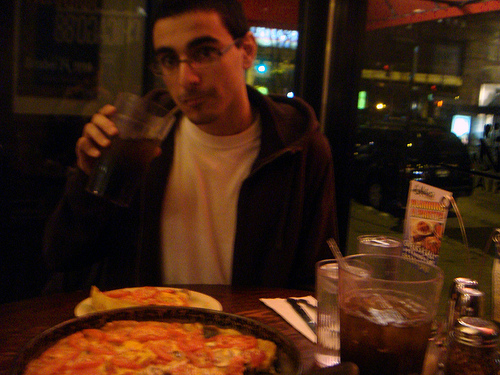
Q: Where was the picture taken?
A: It was taken at the restaurant.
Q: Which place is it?
A: It is a restaurant.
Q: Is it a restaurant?
A: Yes, it is a restaurant.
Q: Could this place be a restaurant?
A: Yes, it is a restaurant.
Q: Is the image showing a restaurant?
A: Yes, it is showing a restaurant.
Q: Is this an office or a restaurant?
A: It is a restaurant.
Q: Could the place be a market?
A: No, it is a restaurant.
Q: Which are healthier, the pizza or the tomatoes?
A: The tomatoes are healthier than the pizza.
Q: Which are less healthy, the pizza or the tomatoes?
A: The pizza are less healthy than the tomatoes.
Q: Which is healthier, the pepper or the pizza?
A: The pepper is healthier than the pizza.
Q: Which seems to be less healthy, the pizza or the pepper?
A: The pizza is less healthy than the pepper.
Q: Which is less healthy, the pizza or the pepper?
A: The pizza is less healthy than the pepper.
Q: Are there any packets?
A: No, there are no packets.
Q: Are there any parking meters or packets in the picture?
A: No, there are no packets or parking meters.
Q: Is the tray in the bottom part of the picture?
A: Yes, the tray is in the bottom of the image.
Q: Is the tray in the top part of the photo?
A: No, the tray is in the bottom of the image.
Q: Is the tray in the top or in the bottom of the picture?
A: The tray is in the bottom of the image.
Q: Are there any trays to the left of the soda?
A: Yes, there is a tray to the left of the soda.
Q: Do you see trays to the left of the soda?
A: Yes, there is a tray to the left of the soda.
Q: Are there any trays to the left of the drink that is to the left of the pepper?
A: Yes, there is a tray to the left of the soda.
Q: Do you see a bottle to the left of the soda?
A: No, there is a tray to the left of the soda.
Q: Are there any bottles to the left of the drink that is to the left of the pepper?
A: No, there is a tray to the left of the soda.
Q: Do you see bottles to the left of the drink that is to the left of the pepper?
A: No, there is a tray to the left of the soda.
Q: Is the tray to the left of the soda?
A: Yes, the tray is to the left of the soda.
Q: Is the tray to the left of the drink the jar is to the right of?
A: Yes, the tray is to the left of the soda.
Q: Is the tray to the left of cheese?
A: No, the tray is to the left of the soda.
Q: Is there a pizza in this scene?
A: Yes, there is a pizza.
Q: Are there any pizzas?
A: Yes, there is a pizza.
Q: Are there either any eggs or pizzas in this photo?
A: Yes, there is a pizza.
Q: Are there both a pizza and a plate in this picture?
A: Yes, there are both a pizza and a plate.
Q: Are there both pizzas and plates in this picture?
A: Yes, there are both a pizza and a plate.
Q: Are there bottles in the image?
A: No, there are no bottles.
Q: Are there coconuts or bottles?
A: No, there are no bottles or coconuts.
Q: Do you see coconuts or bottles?
A: No, there are no bottles or coconuts.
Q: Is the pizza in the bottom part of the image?
A: Yes, the pizza is in the bottom of the image.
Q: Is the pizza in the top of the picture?
A: No, the pizza is in the bottom of the image.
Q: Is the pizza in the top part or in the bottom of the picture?
A: The pizza is in the bottom of the image.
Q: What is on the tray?
A: The pizza is on the tray.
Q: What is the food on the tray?
A: The food is a pizza.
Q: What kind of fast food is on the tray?
A: The food is a pizza.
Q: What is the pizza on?
A: The pizza is on the tray.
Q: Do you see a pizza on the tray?
A: Yes, there is a pizza on the tray.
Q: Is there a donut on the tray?
A: No, there is a pizza on the tray.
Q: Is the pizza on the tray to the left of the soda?
A: Yes, the pizza is on the tray.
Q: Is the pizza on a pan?
A: No, the pizza is on the tray.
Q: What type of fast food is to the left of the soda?
A: The food is a pizza.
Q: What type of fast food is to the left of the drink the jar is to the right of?
A: The food is a pizza.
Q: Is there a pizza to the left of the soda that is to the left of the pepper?
A: Yes, there is a pizza to the left of the soda.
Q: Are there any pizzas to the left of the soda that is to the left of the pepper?
A: Yes, there is a pizza to the left of the soda.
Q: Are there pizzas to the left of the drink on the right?
A: Yes, there is a pizza to the left of the soda.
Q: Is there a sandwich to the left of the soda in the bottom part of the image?
A: No, there is a pizza to the left of the soda.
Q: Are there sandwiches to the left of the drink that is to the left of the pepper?
A: No, there is a pizza to the left of the soda.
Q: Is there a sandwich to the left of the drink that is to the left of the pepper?
A: No, there is a pizza to the left of the soda.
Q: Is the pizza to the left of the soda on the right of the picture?
A: Yes, the pizza is to the left of the soda.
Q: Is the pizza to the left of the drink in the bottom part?
A: Yes, the pizza is to the left of the soda.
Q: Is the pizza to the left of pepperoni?
A: No, the pizza is to the left of the soda.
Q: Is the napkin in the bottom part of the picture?
A: Yes, the napkin is in the bottom of the image.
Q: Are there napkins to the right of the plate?
A: Yes, there is a napkin to the right of the plate.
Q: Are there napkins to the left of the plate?
A: No, the napkin is to the right of the plate.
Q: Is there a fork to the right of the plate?
A: No, there is a napkin to the right of the plate.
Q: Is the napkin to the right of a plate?
A: Yes, the napkin is to the right of a plate.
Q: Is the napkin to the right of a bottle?
A: No, the napkin is to the right of a plate.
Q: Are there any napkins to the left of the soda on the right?
A: Yes, there is a napkin to the left of the soda.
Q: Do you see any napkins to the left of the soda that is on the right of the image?
A: Yes, there is a napkin to the left of the soda.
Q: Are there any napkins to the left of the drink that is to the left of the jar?
A: Yes, there is a napkin to the left of the soda.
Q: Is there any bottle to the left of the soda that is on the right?
A: No, there is a napkin to the left of the soda.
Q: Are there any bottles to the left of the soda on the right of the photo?
A: No, there is a napkin to the left of the soda.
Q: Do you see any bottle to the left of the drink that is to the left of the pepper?
A: No, there is a napkin to the left of the soda.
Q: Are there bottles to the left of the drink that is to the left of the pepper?
A: No, there is a napkin to the left of the soda.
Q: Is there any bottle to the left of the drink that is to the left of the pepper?
A: No, there is a napkin to the left of the soda.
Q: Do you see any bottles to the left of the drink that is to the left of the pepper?
A: No, there is a napkin to the left of the soda.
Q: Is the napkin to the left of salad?
A: No, the napkin is to the left of the soda.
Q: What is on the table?
A: The napkin is on the table.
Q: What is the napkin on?
A: The napkin is on the table.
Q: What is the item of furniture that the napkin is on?
A: The piece of furniture is a table.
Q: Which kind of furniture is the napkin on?
A: The napkin is on the table.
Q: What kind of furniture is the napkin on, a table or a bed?
A: The napkin is on a table.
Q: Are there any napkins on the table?
A: Yes, there is a napkin on the table.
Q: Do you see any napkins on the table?
A: Yes, there is a napkin on the table.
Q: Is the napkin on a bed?
A: No, the napkin is on the table.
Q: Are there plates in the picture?
A: Yes, there is a plate.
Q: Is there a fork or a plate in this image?
A: Yes, there is a plate.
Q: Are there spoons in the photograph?
A: No, there are no spoons.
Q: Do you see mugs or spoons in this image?
A: No, there are no spoons or mugs.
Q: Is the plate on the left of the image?
A: Yes, the plate is on the left of the image.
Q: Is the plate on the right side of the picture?
A: No, the plate is on the left of the image.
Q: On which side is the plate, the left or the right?
A: The plate is on the left of the image.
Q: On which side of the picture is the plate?
A: The plate is on the left of the image.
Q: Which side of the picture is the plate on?
A: The plate is on the left of the image.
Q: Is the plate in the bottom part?
A: Yes, the plate is in the bottom of the image.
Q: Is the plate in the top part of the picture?
A: No, the plate is in the bottom of the image.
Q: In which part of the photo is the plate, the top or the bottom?
A: The plate is in the bottom of the image.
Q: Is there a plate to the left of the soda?
A: Yes, there is a plate to the left of the soda.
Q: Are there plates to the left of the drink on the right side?
A: Yes, there is a plate to the left of the soda.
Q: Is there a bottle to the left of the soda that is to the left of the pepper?
A: No, there is a plate to the left of the soda.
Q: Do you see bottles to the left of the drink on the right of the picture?
A: No, there is a plate to the left of the soda.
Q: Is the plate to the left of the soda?
A: Yes, the plate is to the left of the soda.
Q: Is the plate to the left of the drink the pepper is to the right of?
A: Yes, the plate is to the left of the soda.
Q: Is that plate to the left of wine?
A: No, the plate is to the left of the soda.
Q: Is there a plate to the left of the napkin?
A: Yes, there is a plate to the left of the napkin.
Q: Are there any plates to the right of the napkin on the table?
A: No, the plate is to the left of the napkin.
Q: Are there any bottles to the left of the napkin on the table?
A: No, there is a plate to the left of the napkin.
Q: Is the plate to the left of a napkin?
A: Yes, the plate is to the left of a napkin.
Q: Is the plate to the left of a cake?
A: No, the plate is to the left of a napkin.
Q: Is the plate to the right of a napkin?
A: No, the plate is to the left of a napkin.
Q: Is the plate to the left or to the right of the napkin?
A: The plate is to the left of the napkin.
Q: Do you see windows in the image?
A: Yes, there is a window.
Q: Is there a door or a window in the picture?
A: Yes, there is a window.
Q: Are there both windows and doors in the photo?
A: No, there is a window but no doors.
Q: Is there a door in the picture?
A: No, there are no doors.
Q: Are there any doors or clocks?
A: No, there are no doors or clocks.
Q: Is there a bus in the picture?
A: No, there are no buses.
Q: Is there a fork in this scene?
A: No, there are no forks.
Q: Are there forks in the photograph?
A: No, there are no forks.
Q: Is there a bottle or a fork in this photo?
A: No, there are no forks or bottles.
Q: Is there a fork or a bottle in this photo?
A: No, there are no forks or bottles.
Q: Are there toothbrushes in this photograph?
A: No, there are no toothbrushes.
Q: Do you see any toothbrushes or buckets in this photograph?
A: No, there are no toothbrushes or buckets.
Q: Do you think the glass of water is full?
A: Yes, the glass is full.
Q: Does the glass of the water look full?
A: Yes, the glass is full.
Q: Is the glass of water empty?
A: No, the glass is full.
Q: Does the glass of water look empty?
A: No, the glass is full.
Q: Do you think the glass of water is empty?
A: No, the glass is full.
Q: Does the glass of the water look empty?
A: No, the glass is full.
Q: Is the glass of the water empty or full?
A: The glass is full.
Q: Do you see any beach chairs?
A: No, there are no beach chairs.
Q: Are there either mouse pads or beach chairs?
A: No, there are no beach chairs or mouse pads.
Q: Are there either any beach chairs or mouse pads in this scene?
A: No, there are no beach chairs or mouse pads.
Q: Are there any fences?
A: No, there are no fences.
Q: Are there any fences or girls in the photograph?
A: No, there are no fences or girls.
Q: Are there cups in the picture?
A: Yes, there is a cup.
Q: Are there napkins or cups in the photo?
A: Yes, there is a cup.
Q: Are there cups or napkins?
A: Yes, there is a cup.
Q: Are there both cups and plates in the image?
A: Yes, there are both a cup and a plate.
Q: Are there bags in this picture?
A: No, there are no bags.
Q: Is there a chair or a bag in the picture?
A: No, there are no bags or chairs.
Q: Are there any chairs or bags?
A: No, there are no bags or chairs.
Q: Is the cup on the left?
A: Yes, the cup is on the left of the image.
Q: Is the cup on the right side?
A: No, the cup is on the left of the image.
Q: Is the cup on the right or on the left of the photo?
A: The cup is on the left of the image.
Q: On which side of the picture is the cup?
A: The cup is on the left of the image.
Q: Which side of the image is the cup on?
A: The cup is on the left of the image.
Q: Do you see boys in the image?
A: No, there are no boys.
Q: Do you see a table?
A: Yes, there is a table.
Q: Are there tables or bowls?
A: Yes, there is a table.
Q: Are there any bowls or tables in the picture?
A: Yes, there is a table.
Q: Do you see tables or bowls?
A: Yes, there is a table.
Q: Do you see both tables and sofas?
A: No, there is a table but no sofas.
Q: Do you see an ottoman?
A: No, there are no ottomen.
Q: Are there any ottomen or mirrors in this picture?
A: No, there are no ottomen or mirrors.